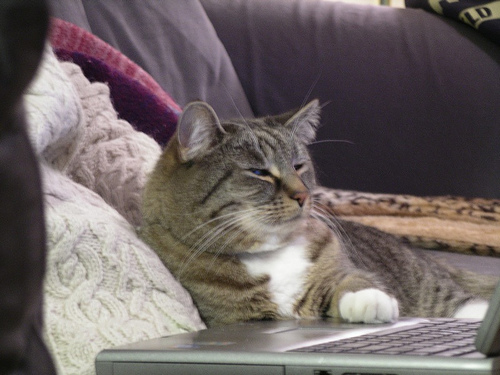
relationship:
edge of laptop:
[91, 351, 191, 369] [86, 294, 498, 375]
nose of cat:
[287, 186, 312, 210] [137, 90, 495, 322]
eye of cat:
[247, 167, 271, 179] [137, 90, 495, 322]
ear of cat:
[173, 96, 229, 166] [137, 90, 495, 322]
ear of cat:
[273, 96, 325, 152] [137, 90, 495, 322]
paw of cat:
[338, 286, 409, 327] [137, 90, 495, 322]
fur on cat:
[239, 233, 314, 319] [137, 90, 495, 322]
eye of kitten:
[247, 167, 271, 179] [137, 90, 495, 322]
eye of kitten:
[290, 160, 309, 174] [137, 90, 495, 322]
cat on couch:
[137, 90, 495, 322] [49, 3, 499, 323]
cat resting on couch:
[137, 90, 495, 322] [49, 3, 499, 323]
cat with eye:
[137, 90, 495, 322] [247, 167, 271, 179]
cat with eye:
[137, 90, 495, 322] [290, 160, 309, 174]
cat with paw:
[137, 90, 495, 322] [338, 286, 409, 327]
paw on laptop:
[338, 286, 409, 327] [86, 294, 498, 375]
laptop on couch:
[86, 294, 498, 375] [49, 3, 499, 323]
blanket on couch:
[48, 16, 182, 145] [49, 3, 499, 323]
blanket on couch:
[15, 36, 185, 375] [49, 3, 499, 323]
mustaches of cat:
[249, 206, 280, 222] [137, 90, 495, 322]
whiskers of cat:
[175, 203, 278, 276] [137, 90, 495, 322]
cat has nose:
[137, 90, 495, 322] [287, 186, 312, 210]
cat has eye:
[137, 90, 495, 322] [247, 167, 271, 179]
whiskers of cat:
[310, 196, 362, 260] [137, 90, 495, 322]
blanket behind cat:
[15, 36, 185, 375] [137, 90, 495, 322]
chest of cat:
[239, 233, 314, 319] [137, 90, 495, 322]